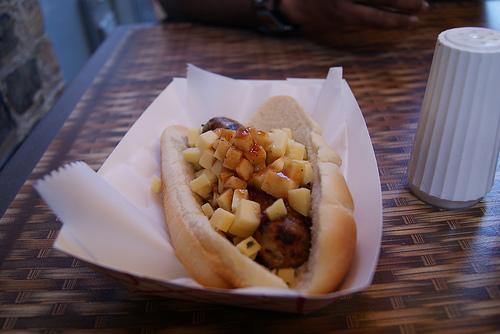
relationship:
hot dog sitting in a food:
[203, 114, 312, 266] [159, 94, 358, 295]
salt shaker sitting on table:
[403, 25, 499, 212] [1, 26, 497, 334]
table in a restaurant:
[1, 26, 497, 334] [3, 1, 499, 334]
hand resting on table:
[272, 0, 430, 49] [1, 26, 497, 334]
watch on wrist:
[250, 0, 299, 37] [235, 0, 306, 36]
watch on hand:
[250, 0, 299, 37] [272, 0, 430, 49]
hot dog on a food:
[203, 114, 312, 266] [159, 94, 358, 295]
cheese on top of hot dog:
[235, 235, 260, 259] [203, 114, 312, 266]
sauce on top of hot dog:
[217, 130, 275, 184] [203, 114, 312, 266]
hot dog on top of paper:
[203, 114, 312, 266] [33, 62, 348, 287]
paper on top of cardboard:
[33, 62, 348, 287] [51, 76, 384, 314]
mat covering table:
[1, 23, 499, 331] [1, 26, 497, 334]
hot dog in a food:
[203, 114, 311, 270] [159, 94, 358, 295]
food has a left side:
[159, 94, 358, 295] [157, 123, 290, 290]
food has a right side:
[159, 94, 358, 295] [248, 94, 356, 297]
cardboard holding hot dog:
[51, 76, 384, 314] [203, 114, 311, 270]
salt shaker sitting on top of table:
[403, 25, 499, 212] [1, 26, 497, 334]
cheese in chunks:
[187, 128, 317, 258] [199, 137, 295, 193]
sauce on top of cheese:
[217, 130, 275, 184] [187, 128, 317, 258]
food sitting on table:
[159, 94, 358, 300] [1, 26, 497, 334]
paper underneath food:
[33, 62, 348, 287] [159, 94, 358, 295]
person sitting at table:
[150, 0, 433, 53] [1, 26, 497, 334]